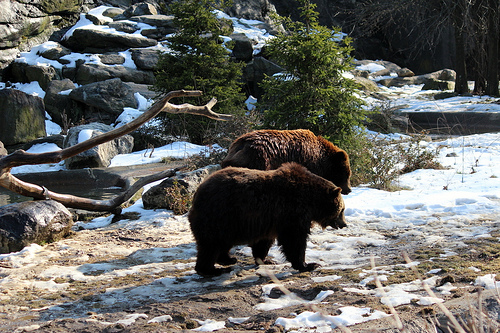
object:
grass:
[250, 252, 499, 332]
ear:
[329, 185, 342, 202]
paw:
[303, 261, 320, 274]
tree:
[0, 89, 234, 171]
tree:
[0, 166, 182, 215]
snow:
[273, 305, 392, 332]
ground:
[1, 130, 499, 330]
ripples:
[313, 217, 382, 260]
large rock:
[0, 199, 75, 256]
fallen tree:
[0, 154, 213, 217]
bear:
[213, 126, 353, 198]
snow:
[70, 131, 499, 286]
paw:
[262, 254, 275, 265]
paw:
[216, 254, 239, 267]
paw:
[206, 265, 232, 278]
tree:
[250, 0, 378, 186]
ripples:
[79, 183, 98, 200]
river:
[0, 187, 126, 210]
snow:
[12, 40, 139, 73]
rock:
[0, 51, 60, 93]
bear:
[187, 163, 351, 278]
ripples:
[438, 113, 466, 132]